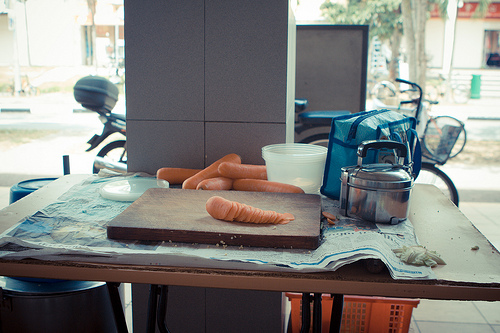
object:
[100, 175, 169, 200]
lid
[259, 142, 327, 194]
container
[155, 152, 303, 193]
carrots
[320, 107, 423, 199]
bag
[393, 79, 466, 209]
bicycle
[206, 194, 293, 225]
carrot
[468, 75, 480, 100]
can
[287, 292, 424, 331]
crate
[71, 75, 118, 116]
helmet carrier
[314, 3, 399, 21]
green tree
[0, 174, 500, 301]
surface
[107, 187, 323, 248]
board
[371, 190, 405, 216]
metal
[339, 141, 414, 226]
pot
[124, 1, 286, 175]
grey column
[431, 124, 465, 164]
newspaper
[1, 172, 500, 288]
table top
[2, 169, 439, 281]
newspaper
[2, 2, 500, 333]
outside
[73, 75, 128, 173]
bike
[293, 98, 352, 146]
bike